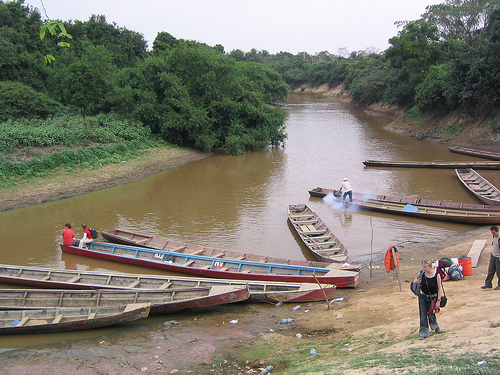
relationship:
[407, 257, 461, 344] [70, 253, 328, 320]
woman standing by canoes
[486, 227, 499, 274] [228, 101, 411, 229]
man near water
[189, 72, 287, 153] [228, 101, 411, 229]
trees by water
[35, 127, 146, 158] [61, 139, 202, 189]
bushes on shore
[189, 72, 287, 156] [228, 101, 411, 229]
trees in water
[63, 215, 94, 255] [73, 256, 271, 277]
people on canoe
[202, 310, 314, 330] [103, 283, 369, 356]
bottles on shore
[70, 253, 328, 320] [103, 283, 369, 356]
canoes on shore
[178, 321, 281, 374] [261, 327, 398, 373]
trash on ground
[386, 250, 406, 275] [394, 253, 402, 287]
jacket on post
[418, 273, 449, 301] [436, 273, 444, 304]
top has no sleeves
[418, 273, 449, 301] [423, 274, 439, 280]
top has a round collar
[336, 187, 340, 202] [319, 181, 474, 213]
engine of boat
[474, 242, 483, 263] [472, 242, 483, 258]
wooden plank sidewalk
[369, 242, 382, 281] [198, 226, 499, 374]
stake in ground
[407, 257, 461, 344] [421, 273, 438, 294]
woman wearing black tank top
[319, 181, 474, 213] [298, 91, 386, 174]
boat in river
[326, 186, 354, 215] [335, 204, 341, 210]
ma pouring water